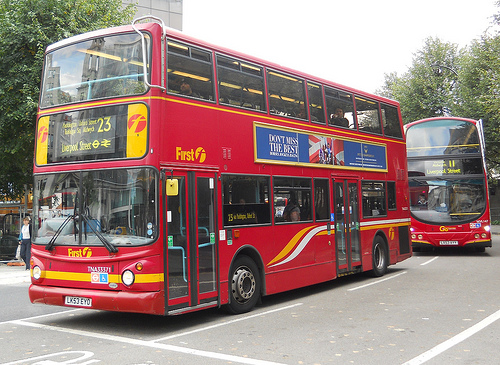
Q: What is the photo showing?
A: It is showing a street.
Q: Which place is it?
A: It is a street.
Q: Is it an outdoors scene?
A: Yes, it is outdoors.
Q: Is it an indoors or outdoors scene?
A: It is outdoors.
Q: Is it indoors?
A: No, it is outdoors.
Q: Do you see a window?
A: Yes, there is a window.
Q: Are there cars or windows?
A: Yes, there is a window.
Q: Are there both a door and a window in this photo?
A: Yes, there are both a window and a door.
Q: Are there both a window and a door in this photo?
A: Yes, there are both a window and a door.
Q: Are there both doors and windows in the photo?
A: Yes, there are both a window and a door.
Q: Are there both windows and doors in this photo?
A: Yes, there are both a window and a door.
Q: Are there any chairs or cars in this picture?
A: No, there are no cars or chairs.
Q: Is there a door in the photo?
A: Yes, there is a door.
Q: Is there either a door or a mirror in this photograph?
A: Yes, there is a door.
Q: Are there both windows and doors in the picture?
A: Yes, there are both a door and a window.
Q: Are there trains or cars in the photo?
A: No, there are no trains or cars.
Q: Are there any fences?
A: No, there are no fences.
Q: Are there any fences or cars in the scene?
A: No, there are no fences or cars.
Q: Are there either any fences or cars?
A: No, there are no cars or fences.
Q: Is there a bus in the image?
A: Yes, there is a bus.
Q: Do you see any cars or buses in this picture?
A: Yes, there is a bus.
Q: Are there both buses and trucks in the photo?
A: No, there is a bus but no trucks.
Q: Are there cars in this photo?
A: No, there are no cars.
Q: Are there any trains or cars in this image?
A: No, there are no cars or trains.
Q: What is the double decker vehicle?
A: The vehicle is a bus.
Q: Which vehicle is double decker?
A: The vehicle is a bus.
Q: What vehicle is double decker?
A: The vehicle is a bus.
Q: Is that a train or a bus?
A: That is a bus.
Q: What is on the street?
A: The bus is on the street.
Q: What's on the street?
A: The bus is on the street.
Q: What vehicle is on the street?
A: The vehicle is a bus.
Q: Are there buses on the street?
A: Yes, there is a bus on the street.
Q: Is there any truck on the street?
A: No, there is a bus on the street.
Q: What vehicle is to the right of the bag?
A: The vehicle is a bus.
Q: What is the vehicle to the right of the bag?
A: The vehicle is a bus.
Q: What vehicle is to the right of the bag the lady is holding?
A: The vehicle is a bus.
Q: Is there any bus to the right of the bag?
A: Yes, there is a bus to the right of the bag.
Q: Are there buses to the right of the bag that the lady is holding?
A: Yes, there is a bus to the right of the bag.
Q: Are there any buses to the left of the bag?
A: No, the bus is to the right of the bag.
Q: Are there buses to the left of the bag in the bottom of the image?
A: No, the bus is to the right of the bag.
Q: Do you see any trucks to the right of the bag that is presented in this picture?
A: No, there is a bus to the right of the bag.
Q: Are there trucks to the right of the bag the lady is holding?
A: No, there is a bus to the right of the bag.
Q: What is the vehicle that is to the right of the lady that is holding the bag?
A: The vehicle is a bus.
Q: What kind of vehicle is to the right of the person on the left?
A: The vehicle is a bus.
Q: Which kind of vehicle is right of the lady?
A: The vehicle is a bus.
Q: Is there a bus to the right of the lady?
A: Yes, there is a bus to the right of the lady.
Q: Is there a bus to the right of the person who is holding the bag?
A: Yes, there is a bus to the right of the lady.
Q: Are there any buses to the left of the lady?
A: No, the bus is to the right of the lady.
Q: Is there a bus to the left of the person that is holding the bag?
A: No, the bus is to the right of the lady.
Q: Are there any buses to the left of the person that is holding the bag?
A: No, the bus is to the right of the lady.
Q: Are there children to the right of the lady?
A: No, there is a bus to the right of the lady.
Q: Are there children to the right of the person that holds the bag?
A: No, there is a bus to the right of the lady.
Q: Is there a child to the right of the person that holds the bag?
A: No, there is a bus to the right of the lady.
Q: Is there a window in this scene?
A: Yes, there is a window.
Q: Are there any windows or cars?
A: Yes, there is a window.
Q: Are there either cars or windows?
A: Yes, there is a window.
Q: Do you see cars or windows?
A: Yes, there is a window.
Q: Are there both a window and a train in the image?
A: No, there is a window but no trains.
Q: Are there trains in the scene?
A: No, there are no trains.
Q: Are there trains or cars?
A: No, there are no trains or cars.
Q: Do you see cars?
A: No, there are no cars.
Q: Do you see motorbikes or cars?
A: No, there are no cars or motorbikes.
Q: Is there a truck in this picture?
A: No, there are no trucks.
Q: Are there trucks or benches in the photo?
A: No, there are no trucks or benches.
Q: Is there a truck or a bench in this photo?
A: No, there are no trucks or benches.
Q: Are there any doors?
A: Yes, there is a door.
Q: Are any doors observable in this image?
A: Yes, there is a door.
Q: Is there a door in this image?
A: Yes, there is a door.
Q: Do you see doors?
A: Yes, there is a door.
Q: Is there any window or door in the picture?
A: Yes, there is a door.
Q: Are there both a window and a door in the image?
A: Yes, there are both a door and a window.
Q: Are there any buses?
A: Yes, there is a bus.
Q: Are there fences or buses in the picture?
A: Yes, there is a bus.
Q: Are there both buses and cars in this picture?
A: No, there is a bus but no cars.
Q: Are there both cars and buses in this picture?
A: No, there is a bus but no cars.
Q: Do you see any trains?
A: No, there are no trains.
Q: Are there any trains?
A: No, there are no trains.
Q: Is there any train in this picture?
A: No, there are no trains.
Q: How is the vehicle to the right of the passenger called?
A: The vehicle is a bus.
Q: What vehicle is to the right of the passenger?
A: The vehicle is a bus.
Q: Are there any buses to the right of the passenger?
A: Yes, there is a bus to the right of the passenger.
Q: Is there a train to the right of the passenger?
A: No, there is a bus to the right of the passenger.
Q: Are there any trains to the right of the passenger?
A: No, there is a bus to the right of the passenger.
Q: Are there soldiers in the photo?
A: No, there are no soldiers.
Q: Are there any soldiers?
A: No, there are no soldiers.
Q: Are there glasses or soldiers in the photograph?
A: No, there are no soldiers or glasses.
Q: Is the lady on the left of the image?
A: Yes, the lady is on the left of the image.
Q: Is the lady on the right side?
A: No, the lady is on the left of the image.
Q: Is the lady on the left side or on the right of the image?
A: The lady is on the left of the image.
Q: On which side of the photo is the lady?
A: The lady is on the left of the image.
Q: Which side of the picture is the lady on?
A: The lady is on the left of the image.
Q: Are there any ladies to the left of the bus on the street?
A: Yes, there is a lady to the left of the bus.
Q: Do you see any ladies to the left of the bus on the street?
A: Yes, there is a lady to the left of the bus.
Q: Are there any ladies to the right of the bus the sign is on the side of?
A: No, the lady is to the left of the bus.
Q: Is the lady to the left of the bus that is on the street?
A: Yes, the lady is to the left of the bus.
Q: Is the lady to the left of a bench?
A: No, the lady is to the left of the bus.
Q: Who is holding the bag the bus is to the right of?
A: The lady is holding the bag.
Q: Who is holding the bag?
A: The lady is holding the bag.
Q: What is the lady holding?
A: The lady is holding the bag.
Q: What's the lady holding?
A: The lady is holding the bag.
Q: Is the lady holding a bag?
A: Yes, the lady is holding a bag.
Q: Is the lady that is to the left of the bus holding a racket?
A: No, the lady is holding a bag.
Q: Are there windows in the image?
A: Yes, there is a window.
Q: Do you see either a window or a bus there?
A: Yes, there is a window.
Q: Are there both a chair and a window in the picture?
A: No, there is a window but no chairs.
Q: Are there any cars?
A: No, there are no cars.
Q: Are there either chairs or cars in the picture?
A: No, there are no cars or chairs.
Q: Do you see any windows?
A: Yes, there is a window.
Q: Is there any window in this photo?
A: Yes, there is a window.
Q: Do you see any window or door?
A: Yes, there is a window.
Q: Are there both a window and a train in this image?
A: No, there is a window but no trains.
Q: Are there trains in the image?
A: No, there are no trains.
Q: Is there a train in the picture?
A: No, there are no trains.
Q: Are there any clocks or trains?
A: No, there are no trains or clocks.